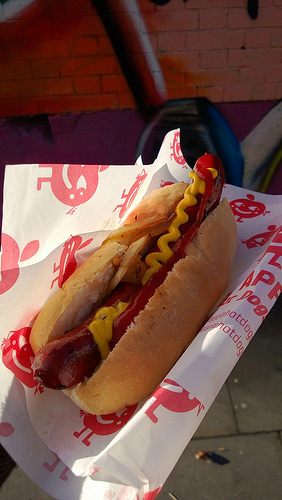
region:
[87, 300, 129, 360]
mustard on top of the hotdog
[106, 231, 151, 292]
grilled onions on the hotdog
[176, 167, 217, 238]
mustard and ketchup on the hotdog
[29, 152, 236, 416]
a hotdog on a toasted hoagie roll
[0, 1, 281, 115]
a brick wall in the back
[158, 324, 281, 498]
a grey tiled floor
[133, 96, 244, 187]
a black chair near the table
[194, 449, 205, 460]
food crumbs on the tiled floor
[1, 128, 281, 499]
the company name on the white and red wrapping paper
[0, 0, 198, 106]
painted graffiti on the back wall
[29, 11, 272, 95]
the wall is bricks.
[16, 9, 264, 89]
the bricks are red.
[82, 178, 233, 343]
ketchup and mustard on hot dog.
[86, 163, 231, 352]
the mustard is yellow.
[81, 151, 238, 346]
the ketchup is red.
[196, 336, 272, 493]
the ground is grey.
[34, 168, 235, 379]
the bun is tan.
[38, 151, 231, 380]
the hot dog is pink.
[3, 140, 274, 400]
the hot dog is on paper.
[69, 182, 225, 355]
onions on a hot dog.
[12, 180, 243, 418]
a hot dog sitting on a paper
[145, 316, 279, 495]
the ground below the hot dog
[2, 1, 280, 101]
the fence next to the hot dog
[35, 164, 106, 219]
the happy apple on the paper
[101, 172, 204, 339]
mustard and ketchup on the hot dog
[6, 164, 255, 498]
the paper under the hot dog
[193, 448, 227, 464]
some trash on the ground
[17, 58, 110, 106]
some bricks on the ground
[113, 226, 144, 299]
some onion on the hot dog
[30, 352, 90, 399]
the end of the hot dog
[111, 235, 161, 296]
Onions on the hot dog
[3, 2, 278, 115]
Red brick wall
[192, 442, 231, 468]
A leaf is on the sidewalk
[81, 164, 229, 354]
Ketchup and mustard are on the hot dog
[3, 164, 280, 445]
White wrapper printed with red apples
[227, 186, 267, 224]
The red apples are smiling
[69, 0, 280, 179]
Graffiti is on the wall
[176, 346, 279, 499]
The sidewalk is grey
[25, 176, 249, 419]
Hardy hot dog bun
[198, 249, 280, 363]
Red lettering on the wrapper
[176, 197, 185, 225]
mustard on hot dog.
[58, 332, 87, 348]
ketchup on hot dog.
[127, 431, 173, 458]
white wrapper around hot dog.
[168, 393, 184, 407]
red logo on white wrapper.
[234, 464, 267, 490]
concrete sidewalk on the ground.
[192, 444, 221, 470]
object on the ground.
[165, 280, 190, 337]
bun holding hot dog.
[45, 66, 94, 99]
brick on the wall.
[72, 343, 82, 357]
hot dog in a bun.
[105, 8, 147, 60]
graffiti on the wall.